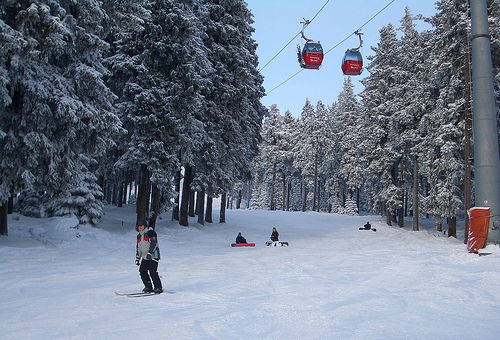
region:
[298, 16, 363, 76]
two red ski lifts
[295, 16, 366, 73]
two side-by-side ski lifts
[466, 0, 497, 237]
large metal pole on the right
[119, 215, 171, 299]
one man cross-country skiing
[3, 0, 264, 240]
snow covered evergreen trees on the left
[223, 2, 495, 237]
more snow-capped trees in background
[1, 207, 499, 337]
blanket of snow on the ground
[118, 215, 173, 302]
man wears black pants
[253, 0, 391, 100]
wires support the gondolas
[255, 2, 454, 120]
sky is bright and sunny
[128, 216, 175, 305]
Boy wearing skiis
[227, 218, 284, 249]
Two people sledding in the snow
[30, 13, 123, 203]
White with snow covered trees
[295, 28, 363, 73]
Two red skylifts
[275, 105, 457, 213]
Beautiful Snow covered trees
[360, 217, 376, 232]
Someone sledding down the hill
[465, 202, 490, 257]
Red safety padding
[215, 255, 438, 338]
Cold white fluffy snow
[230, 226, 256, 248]
Kid on a red sled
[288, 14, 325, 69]
Suspending red skylift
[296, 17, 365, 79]
Two cars on the rail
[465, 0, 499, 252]
Large grey pole with orange mat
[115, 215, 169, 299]
Man wearing snow skis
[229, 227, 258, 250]
Person resting on something red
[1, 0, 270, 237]
Snow-covered pine trees behind skier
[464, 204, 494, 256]
Orange mat leaning on pole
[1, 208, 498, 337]
Snow on the ground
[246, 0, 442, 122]
Blue sky on a clear day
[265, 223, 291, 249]
Person on black and white bobsled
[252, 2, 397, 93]
Wires carrying cars of people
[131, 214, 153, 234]
the head of a person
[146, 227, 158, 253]
the arm of a person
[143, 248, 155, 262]
the hand of a person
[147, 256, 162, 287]
the leg of a person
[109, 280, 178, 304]
a pair of skis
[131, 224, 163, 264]
a gray and red coat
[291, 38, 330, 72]
a red ski lift car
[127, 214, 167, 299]
a person on the skis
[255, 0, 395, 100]
a pair of wires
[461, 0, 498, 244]
a large gray metal pole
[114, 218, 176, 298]
a man wearing winter clothes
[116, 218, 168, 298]
a man skiing down a hill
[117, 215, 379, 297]
a group of skiers and snowboarders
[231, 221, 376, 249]
snowboarders taking a break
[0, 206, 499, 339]
White snowy path through the woods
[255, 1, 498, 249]
red ski lift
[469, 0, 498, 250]
big metal gray pole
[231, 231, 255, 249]
snowboarder with red snowboard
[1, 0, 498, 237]
white winter forest landscape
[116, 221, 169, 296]
man wearing black hat